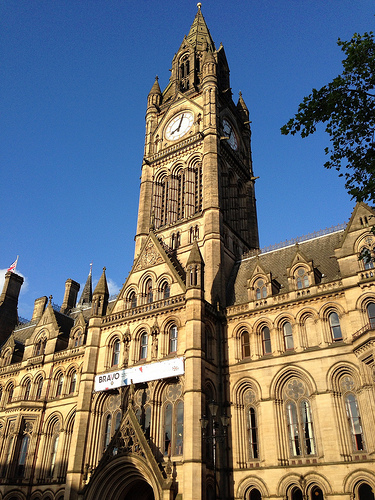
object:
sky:
[0, 0, 375, 318]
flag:
[7, 254, 20, 274]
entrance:
[80, 409, 179, 500]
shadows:
[0, 459, 109, 500]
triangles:
[139, 366, 143, 372]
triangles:
[123, 378, 127, 386]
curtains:
[286, 399, 316, 458]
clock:
[164, 109, 195, 142]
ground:
[330, 122, 334, 127]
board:
[92, 356, 185, 394]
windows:
[0, 316, 185, 477]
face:
[163, 109, 193, 142]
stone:
[202, 135, 218, 155]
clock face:
[222, 118, 241, 152]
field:
[163, 109, 195, 140]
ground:
[277, 107, 302, 146]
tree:
[275, 23, 375, 213]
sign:
[93, 355, 185, 393]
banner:
[94, 356, 185, 393]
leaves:
[278, 25, 374, 209]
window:
[268, 363, 324, 465]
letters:
[99, 372, 120, 383]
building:
[0, 0, 375, 500]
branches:
[288, 78, 375, 163]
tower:
[127, 0, 258, 313]